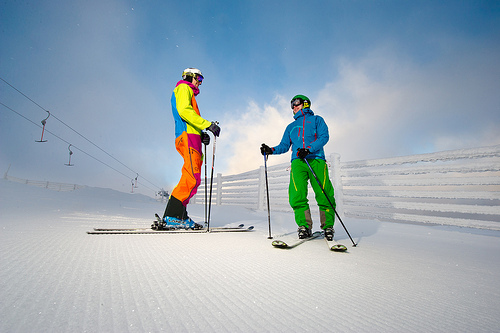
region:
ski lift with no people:
[15, 80, 152, 197]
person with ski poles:
[247, 84, 395, 282]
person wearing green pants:
[247, 93, 376, 300]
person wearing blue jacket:
[244, 81, 364, 183]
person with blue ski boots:
[157, 64, 240, 264]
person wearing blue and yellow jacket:
[145, 51, 239, 142]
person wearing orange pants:
[163, 56, 230, 238]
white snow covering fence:
[359, 127, 499, 252]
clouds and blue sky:
[327, 11, 451, 143]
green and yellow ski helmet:
[277, 88, 337, 128]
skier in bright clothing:
[78, 50, 256, 248]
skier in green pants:
[247, 86, 368, 263]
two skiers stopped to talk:
[69, 46, 371, 271]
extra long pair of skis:
[83, 216, 260, 240]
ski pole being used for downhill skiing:
[254, 142, 274, 247]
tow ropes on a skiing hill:
[20, 88, 145, 197]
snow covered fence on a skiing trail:
[369, 145, 491, 235]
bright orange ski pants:
[166, 130, 207, 221]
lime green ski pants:
[281, 151, 341, 240]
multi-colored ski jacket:
[164, 76, 214, 139]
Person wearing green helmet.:
[293, 87, 324, 126]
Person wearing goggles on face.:
[287, 87, 312, 115]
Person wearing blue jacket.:
[281, 110, 323, 159]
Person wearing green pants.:
[265, 165, 355, 225]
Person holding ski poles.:
[250, 136, 372, 241]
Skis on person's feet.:
[274, 201, 345, 288]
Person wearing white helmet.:
[181, 58, 217, 106]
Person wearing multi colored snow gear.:
[170, 90, 243, 181]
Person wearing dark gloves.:
[193, 117, 242, 174]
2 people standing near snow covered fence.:
[140, 69, 377, 249]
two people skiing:
[80, 47, 365, 277]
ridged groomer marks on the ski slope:
[46, 251, 323, 331]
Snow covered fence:
[190, 140, 499, 244]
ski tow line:
[1, 67, 173, 208]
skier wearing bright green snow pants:
[284, 153, 341, 233]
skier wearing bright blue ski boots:
[159, 212, 202, 231]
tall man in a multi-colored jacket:
[168, 65, 223, 145]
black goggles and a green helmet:
[289, 95, 311, 109]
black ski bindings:
[147, 210, 168, 232]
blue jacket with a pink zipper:
[261, 107, 335, 157]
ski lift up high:
[0, 100, 90, 174]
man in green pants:
[282, 151, 339, 254]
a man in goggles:
[155, 57, 212, 94]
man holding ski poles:
[237, 141, 362, 261]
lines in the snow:
[72, 248, 242, 298]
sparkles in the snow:
[72, 250, 327, 319]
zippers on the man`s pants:
[275, 158, 332, 198]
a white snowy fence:
[345, 147, 493, 233]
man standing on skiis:
[86, 203, 249, 238]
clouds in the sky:
[221, 60, 364, 165]